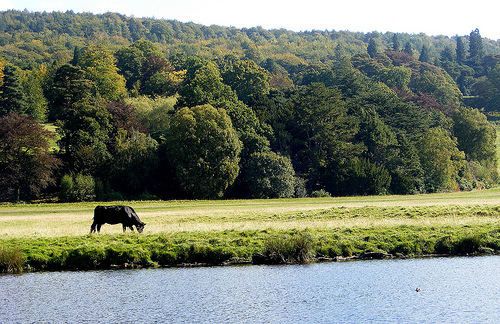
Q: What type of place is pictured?
A: It is a forest.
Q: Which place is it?
A: It is a forest.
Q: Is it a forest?
A: Yes, it is a forest.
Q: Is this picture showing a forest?
A: Yes, it is showing a forest.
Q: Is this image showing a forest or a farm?
A: It is showing a forest.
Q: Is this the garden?
A: No, it is the forest.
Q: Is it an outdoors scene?
A: Yes, it is outdoors.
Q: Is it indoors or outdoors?
A: It is outdoors.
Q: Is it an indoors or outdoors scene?
A: It is outdoors.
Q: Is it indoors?
A: No, it is outdoors.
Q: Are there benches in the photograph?
A: No, there are no benches.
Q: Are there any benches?
A: No, there are no benches.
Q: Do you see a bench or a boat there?
A: No, there are no benches or boats.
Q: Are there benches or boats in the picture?
A: No, there are no benches or boats.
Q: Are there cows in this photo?
A: Yes, there is a cow.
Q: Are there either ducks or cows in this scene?
A: Yes, there is a cow.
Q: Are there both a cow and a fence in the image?
A: No, there is a cow but no fences.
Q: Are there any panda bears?
A: No, there are no panda bears.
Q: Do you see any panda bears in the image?
A: No, there are no panda bears.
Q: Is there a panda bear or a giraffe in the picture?
A: No, there are no panda bears or giraffes.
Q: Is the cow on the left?
A: Yes, the cow is on the left of the image.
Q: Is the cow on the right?
A: No, the cow is on the left of the image.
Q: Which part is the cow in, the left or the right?
A: The cow is on the left of the image.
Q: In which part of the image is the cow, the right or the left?
A: The cow is on the left of the image.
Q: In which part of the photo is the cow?
A: The cow is on the left of the image.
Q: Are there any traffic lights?
A: No, there are no traffic lights.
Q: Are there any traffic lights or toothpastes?
A: No, there are no traffic lights or toothpastes.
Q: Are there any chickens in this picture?
A: No, there are no chickens.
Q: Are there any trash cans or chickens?
A: No, there are no chickens or trash cans.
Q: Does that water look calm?
A: Yes, the water is calm.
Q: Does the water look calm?
A: Yes, the water is calm.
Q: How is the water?
A: The water is calm.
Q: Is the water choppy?
A: No, the water is calm.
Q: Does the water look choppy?
A: No, the water is calm.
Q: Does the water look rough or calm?
A: The water is calm.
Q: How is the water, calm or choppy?
A: The water is calm.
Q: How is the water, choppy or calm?
A: The water is calm.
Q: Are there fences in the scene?
A: No, there are no fences.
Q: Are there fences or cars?
A: No, there are no fences or cars.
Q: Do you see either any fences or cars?
A: No, there are no fences or cars.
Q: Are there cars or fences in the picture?
A: No, there are no fences or cars.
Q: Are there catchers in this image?
A: No, there are no catchers.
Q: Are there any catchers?
A: No, there are no catchers.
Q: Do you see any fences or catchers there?
A: No, there are no catchers or fences.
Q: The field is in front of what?
A: The field is in front of the trees.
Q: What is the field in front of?
A: The field is in front of the trees.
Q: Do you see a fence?
A: No, there are no fences.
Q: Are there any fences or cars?
A: No, there are no fences or cars.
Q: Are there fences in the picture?
A: No, there are no fences.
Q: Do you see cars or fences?
A: No, there are no fences or cars.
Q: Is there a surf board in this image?
A: No, there are no surfboards.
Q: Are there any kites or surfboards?
A: No, there are no surfboards or kites.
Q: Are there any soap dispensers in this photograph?
A: No, there are no soap dispensers.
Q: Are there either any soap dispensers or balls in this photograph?
A: No, there are no soap dispensers or balls.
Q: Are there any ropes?
A: No, there are no ropes.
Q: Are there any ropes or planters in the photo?
A: No, there are no ropes or planters.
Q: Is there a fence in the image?
A: No, there are no fences.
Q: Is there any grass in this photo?
A: Yes, there is grass.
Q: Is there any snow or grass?
A: Yes, there is grass.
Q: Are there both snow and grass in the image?
A: No, there is grass but no snow.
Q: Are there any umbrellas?
A: No, there are no umbrellas.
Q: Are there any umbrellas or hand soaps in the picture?
A: No, there are no umbrellas or hand soaps.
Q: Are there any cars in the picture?
A: No, there are no cars.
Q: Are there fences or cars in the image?
A: No, there are no cars or fences.